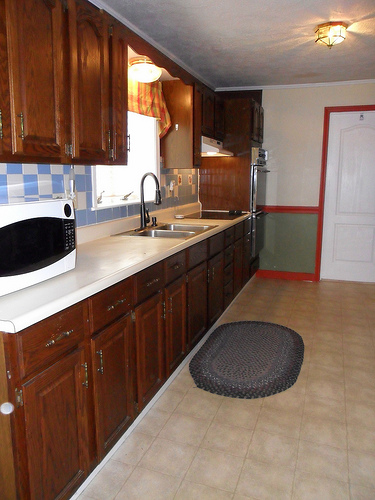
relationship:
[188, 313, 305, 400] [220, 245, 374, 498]
mat on floor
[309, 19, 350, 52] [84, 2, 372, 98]
light on ceiling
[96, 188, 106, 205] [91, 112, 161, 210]
handle on window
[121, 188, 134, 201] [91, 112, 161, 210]
handle on window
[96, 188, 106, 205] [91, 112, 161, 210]
handle controls window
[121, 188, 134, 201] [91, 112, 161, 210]
handle controls window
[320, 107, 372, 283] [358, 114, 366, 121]
door has hook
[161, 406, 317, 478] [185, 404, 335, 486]
kitchen floor has pattern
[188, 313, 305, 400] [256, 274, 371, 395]
mat on floor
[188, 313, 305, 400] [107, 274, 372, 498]
mat on floor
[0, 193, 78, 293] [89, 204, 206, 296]
microwave on counter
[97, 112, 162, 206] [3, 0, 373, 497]
window in kitchen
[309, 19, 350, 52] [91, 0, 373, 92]
light on ceiling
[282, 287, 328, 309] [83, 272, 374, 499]
tile on floor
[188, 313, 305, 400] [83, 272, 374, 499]
mat on floor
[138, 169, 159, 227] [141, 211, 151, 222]
faucet with handle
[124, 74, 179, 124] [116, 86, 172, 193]
curtains on window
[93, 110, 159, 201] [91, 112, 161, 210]
light shines in window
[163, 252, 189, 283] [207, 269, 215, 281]
drawer has hardware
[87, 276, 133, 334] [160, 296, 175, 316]
drawer has hardware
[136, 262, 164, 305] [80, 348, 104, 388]
drawer has hardware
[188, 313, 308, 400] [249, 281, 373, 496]
mat on floor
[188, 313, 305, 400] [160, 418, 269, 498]
mat on floor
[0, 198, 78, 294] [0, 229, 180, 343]
microwave on counter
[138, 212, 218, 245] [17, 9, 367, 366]
sink in kitchen